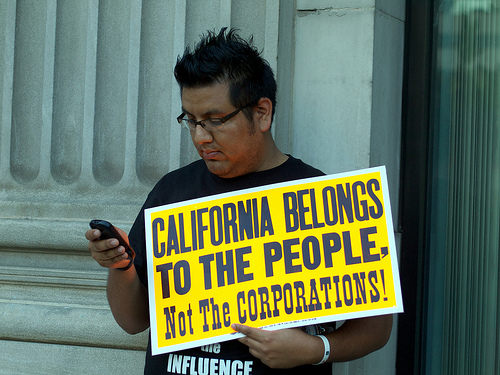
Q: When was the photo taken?
A: Daytime.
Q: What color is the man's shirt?
A: Black.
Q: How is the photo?
A: Clear.